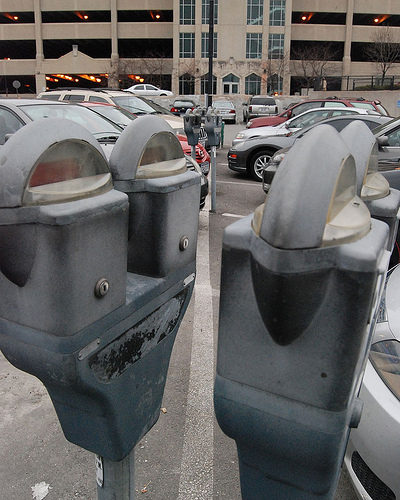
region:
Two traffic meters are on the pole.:
[1, 118, 207, 377]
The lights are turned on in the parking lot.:
[2, 8, 36, 28]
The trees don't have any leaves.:
[278, 47, 336, 92]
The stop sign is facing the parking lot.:
[6, 73, 28, 98]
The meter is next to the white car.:
[332, 228, 398, 450]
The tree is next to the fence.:
[366, 27, 399, 93]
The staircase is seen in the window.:
[247, 1, 280, 28]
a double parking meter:
[10, 130, 194, 380]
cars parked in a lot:
[12, 95, 197, 268]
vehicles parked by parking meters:
[172, 105, 231, 205]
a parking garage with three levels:
[64, 8, 164, 97]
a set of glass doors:
[216, 77, 246, 106]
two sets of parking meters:
[1, 125, 386, 334]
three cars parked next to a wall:
[169, 90, 279, 115]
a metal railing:
[352, 76, 396, 90]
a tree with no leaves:
[367, 20, 392, 82]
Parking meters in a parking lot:
[0, 103, 399, 499]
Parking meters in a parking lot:
[0, 112, 393, 492]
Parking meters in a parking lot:
[3, 112, 392, 487]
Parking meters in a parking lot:
[1, 111, 388, 489]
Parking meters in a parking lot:
[8, 108, 398, 487]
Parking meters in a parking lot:
[9, 108, 393, 490]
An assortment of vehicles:
[234, 104, 277, 158]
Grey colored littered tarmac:
[141, 438, 214, 488]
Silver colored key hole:
[90, 273, 114, 297]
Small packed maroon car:
[248, 111, 281, 127]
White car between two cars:
[236, 126, 267, 138]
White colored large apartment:
[171, 17, 385, 86]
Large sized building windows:
[243, 28, 287, 62]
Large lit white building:
[6, 12, 156, 81]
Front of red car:
[197, 148, 210, 166]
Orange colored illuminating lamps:
[298, 10, 314, 22]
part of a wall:
[196, 430, 208, 472]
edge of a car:
[354, 399, 371, 416]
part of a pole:
[249, 405, 257, 421]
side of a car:
[199, 424, 207, 433]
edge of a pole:
[264, 363, 273, 383]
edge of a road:
[195, 400, 205, 412]